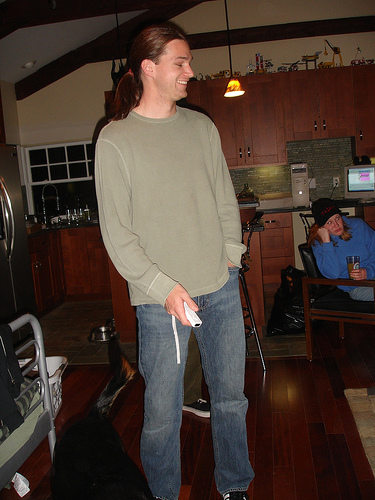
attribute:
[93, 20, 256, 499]
man — smiling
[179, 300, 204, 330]
wii — white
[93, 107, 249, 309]
shirt — green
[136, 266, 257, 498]
jeans — blue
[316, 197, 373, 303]
person — sitting, watching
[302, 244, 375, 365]
chair — black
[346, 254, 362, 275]
cup — orange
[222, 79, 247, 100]
light — hanging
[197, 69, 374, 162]
cabinets — brown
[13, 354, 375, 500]
floor — hardwood, brown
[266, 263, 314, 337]
bag — black, trash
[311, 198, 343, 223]
hat — black, black with red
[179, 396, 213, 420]
shoe — black, white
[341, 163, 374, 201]
monitor — white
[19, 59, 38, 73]
light — off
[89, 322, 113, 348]
dish — empty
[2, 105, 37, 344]
refrigerator — stainless steel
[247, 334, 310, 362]
rug — tan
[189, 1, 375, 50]
beam — dark